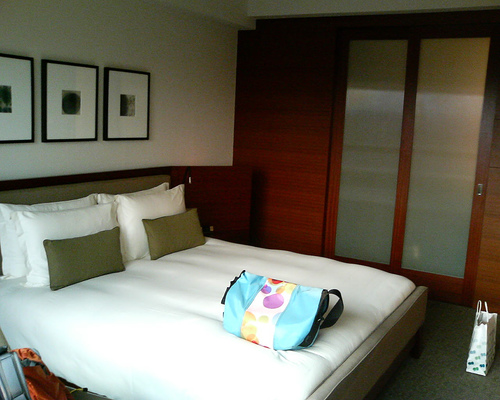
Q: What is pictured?
A: Hotel bed.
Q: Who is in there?
A: No one.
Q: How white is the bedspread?
A: Very bright.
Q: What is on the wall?
A: Picture frames.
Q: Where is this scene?
A: Hotel room.